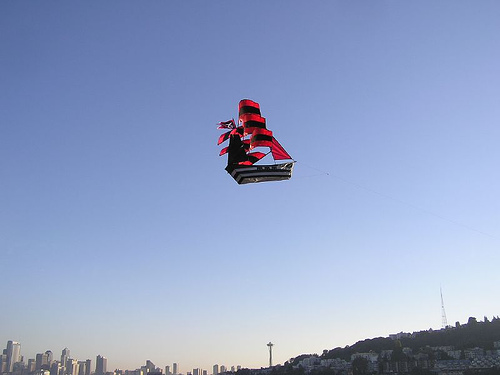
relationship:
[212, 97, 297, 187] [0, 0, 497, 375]
kite flying through blue skies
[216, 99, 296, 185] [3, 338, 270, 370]
kite flying above buildings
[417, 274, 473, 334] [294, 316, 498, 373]
radio on hill